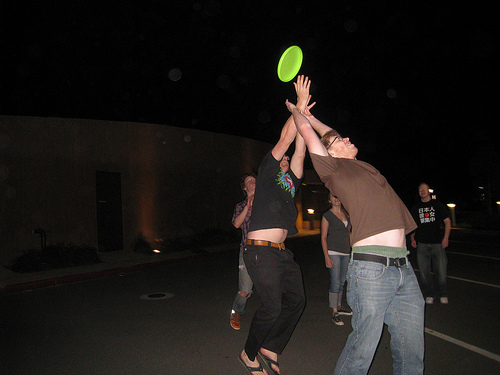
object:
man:
[285, 99, 425, 374]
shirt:
[310, 152, 419, 247]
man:
[240, 75, 316, 375]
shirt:
[248, 151, 306, 236]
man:
[411, 183, 451, 304]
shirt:
[411, 199, 450, 244]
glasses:
[327, 136, 342, 150]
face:
[329, 135, 358, 153]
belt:
[350, 253, 410, 267]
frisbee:
[277, 45, 303, 82]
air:
[0, 1, 499, 230]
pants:
[243, 239, 306, 362]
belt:
[245, 239, 285, 251]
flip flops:
[237, 352, 269, 374]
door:
[96, 172, 124, 253]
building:
[1, 118, 289, 248]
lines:
[422, 328, 499, 362]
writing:
[419, 207, 436, 224]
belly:
[352, 228, 406, 247]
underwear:
[352, 245, 407, 258]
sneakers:
[440, 296, 449, 303]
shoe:
[230, 309, 241, 331]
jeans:
[332, 251, 424, 375]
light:
[153, 249, 161, 253]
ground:
[1, 232, 500, 374]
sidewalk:
[0, 252, 213, 282]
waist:
[352, 228, 406, 259]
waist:
[248, 228, 288, 247]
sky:
[0, 0, 499, 120]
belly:
[248, 228, 289, 244]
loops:
[251, 239, 254, 246]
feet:
[425, 297, 434, 305]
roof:
[1, 112, 280, 125]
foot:
[229, 310, 240, 330]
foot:
[240, 349, 267, 375]